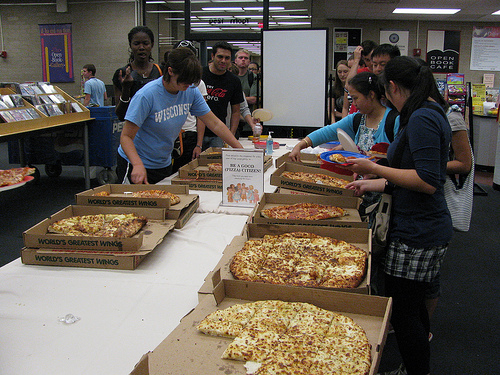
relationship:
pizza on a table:
[230, 231, 370, 287] [2, 137, 321, 374]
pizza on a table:
[50, 214, 145, 234] [2, 137, 321, 374]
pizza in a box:
[260, 199, 348, 222] [252, 192, 370, 225]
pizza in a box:
[285, 169, 354, 188] [267, 159, 366, 191]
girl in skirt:
[342, 56, 455, 372] [384, 236, 447, 284]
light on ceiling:
[394, 8, 462, 15] [313, 2, 499, 25]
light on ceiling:
[492, 10, 500, 18] [313, 2, 499, 25]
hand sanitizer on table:
[266, 130, 276, 153] [2, 137, 321, 374]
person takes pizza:
[288, 71, 403, 163] [285, 169, 354, 188]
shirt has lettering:
[117, 74, 212, 170] [154, 101, 190, 123]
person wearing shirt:
[198, 41, 243, 150] [201, 65, 245, 135]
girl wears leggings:
[342, 56, 455, 372] [387, 277, 432, 372]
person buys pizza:
[234, 49, 262, 135] [50, 214, 145, 234]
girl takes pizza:
[342, 56, 455, 372] [260, 199, 348, 222]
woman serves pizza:
[119, 45, 247, 185] [193, 161, 222, 176]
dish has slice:
[321, 150, 375, 167] [330, 152, 347, 162]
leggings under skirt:
[387, 277, 432, 372] [384, 236, 447, 284]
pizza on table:
[50, 214, 145, 234] [2, 137, 321, 374]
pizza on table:
[205, 297, 371, 374] [2, 137, 321, 374]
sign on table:
[219, 147, 268, 208] [155, 136, 355, 217]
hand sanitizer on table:
[266, 130, 276, 153] [155, 136, 355, 217]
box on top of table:
[22, 204, 166, 251] [2, 137, 321, 374]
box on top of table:
[20, 244, 141, 270] [2, 137, 321, 374]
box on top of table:
[126, 277, 393, 374] [2, 137, 321, 374]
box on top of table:
[205, 223, 374, 290] [2, 137, 321, 374]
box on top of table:
[252, 192, 370, 225] [2, 137, 321, 374]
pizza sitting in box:
[50, 214, 145, 234] [22, 204, 166, 251]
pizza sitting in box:
[205, 297, 371, 374] [126, 277, 393, 374]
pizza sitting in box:
[230, 231, 370, 287] [205, 223, 374, 290]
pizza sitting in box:
[260, 199, 348, 222] [252, 192, 370, 225]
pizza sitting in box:
[285, 169, 354, 188] [267, 159, 366, 191]